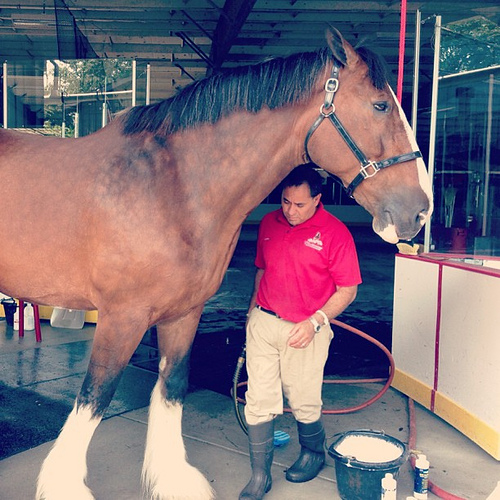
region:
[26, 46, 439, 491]
there is a horse in this shot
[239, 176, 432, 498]
the man appears to be bathing the horse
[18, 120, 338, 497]
the horse is brown, with white feet and a little bit of black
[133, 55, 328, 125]
the horses mane is black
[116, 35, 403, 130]
the horses mane has been trimmed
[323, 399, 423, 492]
this is a bucket of soapy water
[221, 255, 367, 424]
the man is holding a hose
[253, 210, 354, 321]
the man is wearing a red shirt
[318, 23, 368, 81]
this is one of the horses ears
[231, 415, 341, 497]
the man is wearing rubber boots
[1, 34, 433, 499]
horse in a barn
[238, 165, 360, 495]
man getting ready to wash the horse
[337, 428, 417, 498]
bucket of shampoo water for washing the horse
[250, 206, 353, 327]
red shirt on the man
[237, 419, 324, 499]
black boots on the man's feet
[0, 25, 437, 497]
brown horse in a stable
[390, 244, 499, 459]
white, red and yellow wall partition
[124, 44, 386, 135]
black horse hair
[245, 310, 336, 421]
khaki pants on the man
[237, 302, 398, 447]
hose in the man's hand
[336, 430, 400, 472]
black bucket of shampoo for the horse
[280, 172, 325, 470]
man wearing black boots and a red shirt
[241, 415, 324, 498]
black rubber boots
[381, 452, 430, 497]
two bottles of shampoo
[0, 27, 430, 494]
brown and black horse with white legs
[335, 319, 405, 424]
red hose for washing the horse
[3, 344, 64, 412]
wet floor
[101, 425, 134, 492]
gray concrete floor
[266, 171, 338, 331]
man with a black belt and khaki pants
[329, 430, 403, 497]
bucket of soapy water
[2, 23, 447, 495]
horse standing in the stabloe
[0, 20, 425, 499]
brown and white horse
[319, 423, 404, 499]
bucket filled with a white substance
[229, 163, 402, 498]
man carrying a red hose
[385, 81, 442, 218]
white stripe on the head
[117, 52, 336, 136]
black hair laying on the neck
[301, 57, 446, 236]
black bridal on the face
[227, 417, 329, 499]
two black rubber boots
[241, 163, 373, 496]
man standing under the horse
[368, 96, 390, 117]
eye on the side of the head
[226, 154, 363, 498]
a man underneath a horses neck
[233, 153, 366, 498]
a man wearing a pink shirt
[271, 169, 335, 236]
a person looking downwards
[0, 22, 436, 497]
a really tall brown horse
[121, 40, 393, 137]
the short mane of a horse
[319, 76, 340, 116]
the buckle of a harness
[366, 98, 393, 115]
a brown horse eye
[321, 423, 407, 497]
a black bucket with white liquid inside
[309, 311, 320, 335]
a white watch